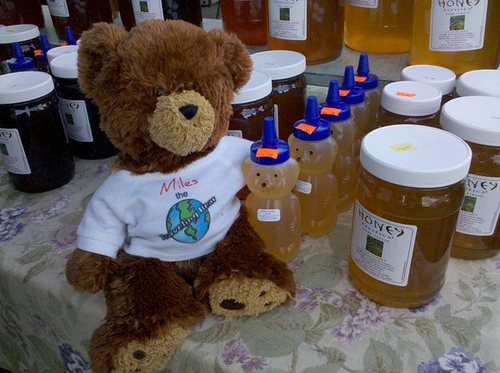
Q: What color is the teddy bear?
A: Brown.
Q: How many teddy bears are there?
A: One.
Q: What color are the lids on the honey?
A: White.